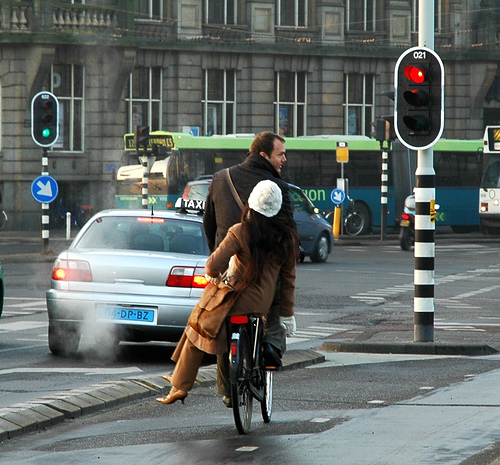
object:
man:
[202, 130, 306, 406]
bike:
[227, 313, 288, 434]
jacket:
[203, 151, 299, 254]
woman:
[156, 178, 296, 404]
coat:
[184, 222, 296, 355]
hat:
[247, 179, 284, 217]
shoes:
[155, 388, 189, 406]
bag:
[188, 280, 240, 339]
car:
[45, 197, 213, 355]